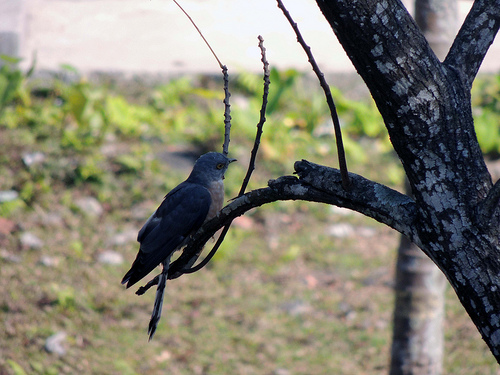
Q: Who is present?
A: Nobody.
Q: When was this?
A: Daytime.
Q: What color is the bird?
A: Grey.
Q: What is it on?
A: A tree.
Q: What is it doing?
A: Resting.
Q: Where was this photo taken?
A: In front of a tree.